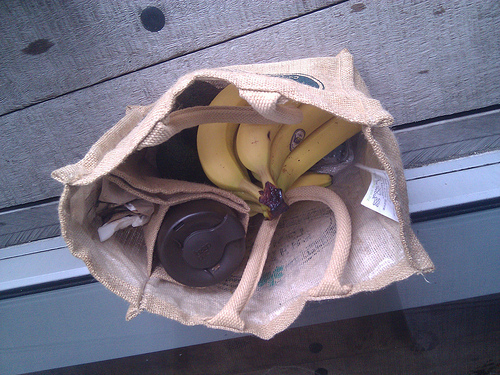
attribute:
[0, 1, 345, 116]
board — worn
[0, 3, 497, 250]
table — wood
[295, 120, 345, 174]
banana — bunched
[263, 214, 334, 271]
ink — showing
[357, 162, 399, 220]
tag — white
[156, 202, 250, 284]
lid — black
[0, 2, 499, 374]
floor — wooden 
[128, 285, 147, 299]
stiches — large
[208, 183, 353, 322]
handle — bag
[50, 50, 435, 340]
bag — light brown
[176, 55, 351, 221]
bananas — yellow 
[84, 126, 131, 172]
bag — open, burlap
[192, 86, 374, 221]
bananas — yellow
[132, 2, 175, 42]
spots — black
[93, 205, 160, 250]
material — rumpled, brown, white